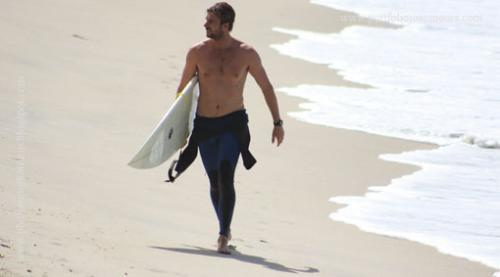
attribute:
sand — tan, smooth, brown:
[0, 256, 444, 276]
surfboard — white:
[128, 68, 200, 171]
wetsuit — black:
[192, 110, 257, 237]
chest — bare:
[200, 42, 246, 86]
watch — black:
[274, 119, 283, 129]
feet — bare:
[217, 234, 231, 254]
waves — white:
[439, 119, 500, 152]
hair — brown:
[206, 3, 235, 30]